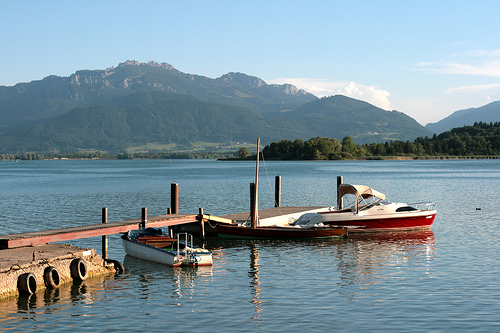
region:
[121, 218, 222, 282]
small boat docked by the boardwalk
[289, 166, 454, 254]
boat docked at the pier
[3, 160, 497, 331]
calm body of water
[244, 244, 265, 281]
reflection in the water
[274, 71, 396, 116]
white cloud visible over the mountaintop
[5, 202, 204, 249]
boardwalk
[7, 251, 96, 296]
row of three circles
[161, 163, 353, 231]
four posts on the pier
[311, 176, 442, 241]
red and white boat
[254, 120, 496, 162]
thick dark green trees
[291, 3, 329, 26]
part of the sky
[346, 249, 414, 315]
part of a water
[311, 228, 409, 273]
part of a reflectiom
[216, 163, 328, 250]
part of a bpart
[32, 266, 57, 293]
part of a wheel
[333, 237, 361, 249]
part of a water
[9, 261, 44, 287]
part of a n edge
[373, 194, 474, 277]
part of a water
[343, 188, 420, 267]
Red and white boat floating in water.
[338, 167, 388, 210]
White covering on boat.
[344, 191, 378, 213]
Metal railings on boat.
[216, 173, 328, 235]
Wood dock near boat.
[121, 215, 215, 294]
White boat near dock.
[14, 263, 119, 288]
Black tires near dock as bumpers.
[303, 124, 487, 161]
Many trees in the distance.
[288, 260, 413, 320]
Water is smooth near boats.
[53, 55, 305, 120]
Large mountain in background.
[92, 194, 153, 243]
Posts sticking out of water near dock.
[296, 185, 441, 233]
boat floating in water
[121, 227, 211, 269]
boat floating in water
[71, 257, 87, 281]
small black rubber tire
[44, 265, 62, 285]
small black rubber tire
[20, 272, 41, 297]
small black rubber tire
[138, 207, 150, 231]
brown wooden dock beam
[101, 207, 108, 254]
brown wooden dock beam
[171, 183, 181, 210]
brown wooden dock beam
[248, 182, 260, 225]
brown wooden dock beam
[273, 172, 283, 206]
brown wooden dock beam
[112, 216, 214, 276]
boat docked at the pier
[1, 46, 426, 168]
mountains in the distance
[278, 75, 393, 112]
puffy white cloud visible over the mountaintop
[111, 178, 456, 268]
two boats that are docked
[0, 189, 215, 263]
boardwalk over the water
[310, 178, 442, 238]
orange and white boat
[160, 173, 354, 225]
four posts on the dock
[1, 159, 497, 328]
large body of water